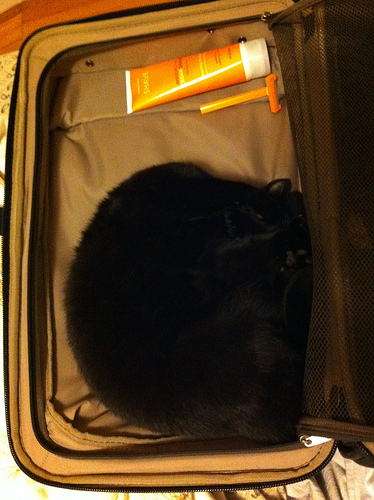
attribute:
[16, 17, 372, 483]
suitcase — cover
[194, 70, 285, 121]
razor — orange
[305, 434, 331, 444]
tab — metal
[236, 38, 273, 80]
whitecap — white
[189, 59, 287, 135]
razor blade — plastic, disposable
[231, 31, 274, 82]
cap — white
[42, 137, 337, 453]
cat — curled up, black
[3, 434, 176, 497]
fabric — printed, white, gold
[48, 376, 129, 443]
stitching — black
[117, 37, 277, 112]
tube — shiny, orange, body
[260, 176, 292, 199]
cat ear — pointed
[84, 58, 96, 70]
button — black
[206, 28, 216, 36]
button — black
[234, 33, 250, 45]
button — black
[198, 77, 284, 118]
shaver — orange, plastic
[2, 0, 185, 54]
floor — wooden, surface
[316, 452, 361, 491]
brown fabric — rumpled, light brown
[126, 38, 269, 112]
product — for beauty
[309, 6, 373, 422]
fabric — mesh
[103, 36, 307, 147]
items — three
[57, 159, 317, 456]
cat — black, sleeping